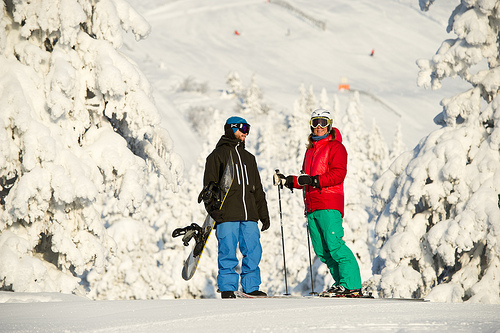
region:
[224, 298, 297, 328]
this is the ground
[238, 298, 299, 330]
the ground is full of snow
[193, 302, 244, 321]
the snow is white in color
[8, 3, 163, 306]
this is a tree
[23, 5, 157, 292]
the tree is tall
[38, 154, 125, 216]
the leaves are covered with snow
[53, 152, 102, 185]
the snow is thick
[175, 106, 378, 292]
these are two people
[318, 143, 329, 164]
the jacket is red in color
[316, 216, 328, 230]
the trouser is green in color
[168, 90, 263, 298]
man in black sweater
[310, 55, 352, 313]
man in red coat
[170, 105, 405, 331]
two man standing on snow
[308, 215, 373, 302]
green pants on man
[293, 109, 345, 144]
snow goggles on man's face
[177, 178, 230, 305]
snow board on man's side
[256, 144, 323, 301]
black ski poles in hand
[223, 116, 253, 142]
black goggles on man's face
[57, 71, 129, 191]
snow on branches of tree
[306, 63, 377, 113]
orange sign on mountain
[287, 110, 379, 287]
this is a man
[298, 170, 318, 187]
this is a glove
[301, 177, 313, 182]
the glove is black in color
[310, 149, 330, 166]
this is a jacket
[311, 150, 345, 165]
the jacket is red in color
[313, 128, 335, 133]
the man is light skinned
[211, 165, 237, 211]
this is a surfboard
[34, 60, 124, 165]
this is a snow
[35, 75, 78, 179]
the snow is white in color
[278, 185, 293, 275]
this is a stick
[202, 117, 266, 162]
the head of a man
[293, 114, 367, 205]
a man wearing a coat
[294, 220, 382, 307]
a man wearing green pants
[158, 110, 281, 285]
a man holding a snowboard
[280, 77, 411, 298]
a man standing on a snow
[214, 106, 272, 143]
a man wearing goggles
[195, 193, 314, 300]
a man wearing blue pants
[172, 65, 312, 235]
a man with a brown coat on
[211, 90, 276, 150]
a man with a blue hat on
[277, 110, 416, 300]
man holding ski poles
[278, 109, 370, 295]
man wearing black boots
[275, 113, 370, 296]
man wearing green pants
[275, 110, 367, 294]
man wearing red coat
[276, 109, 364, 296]
man wearing black gloves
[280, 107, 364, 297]
man wearing white hat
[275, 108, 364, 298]
man wearing ski goggles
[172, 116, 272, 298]
guy wearing blue pants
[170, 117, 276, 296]
guy wearing blue hat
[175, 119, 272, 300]
guy wearing black jacket